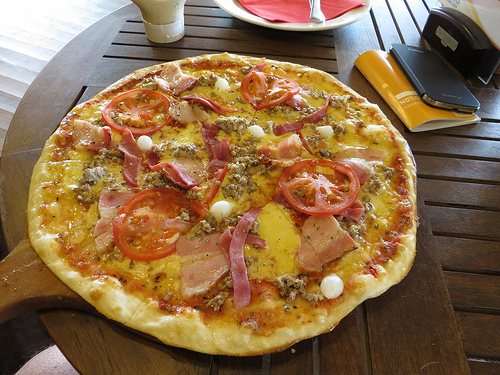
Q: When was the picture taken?
A: Daytime.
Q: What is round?
A: Pizza pie.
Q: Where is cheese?
A: On a pizza.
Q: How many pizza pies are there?
A: One.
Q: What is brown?
A: Table.